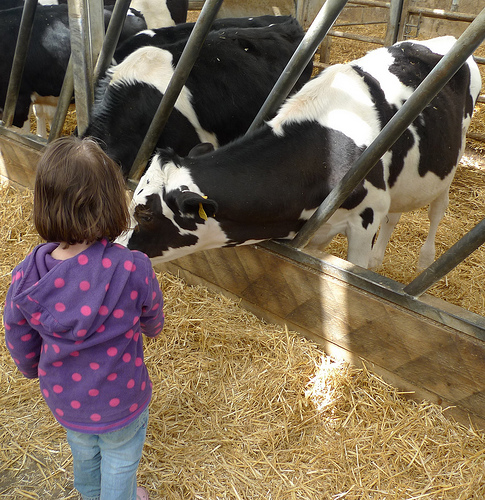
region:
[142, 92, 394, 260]
the cow is white and black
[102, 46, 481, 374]
the cow is white and black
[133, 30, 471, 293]
a black and white cow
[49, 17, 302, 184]
a black and white cow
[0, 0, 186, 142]
a black and white cow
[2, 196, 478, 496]
floor covered in brown hay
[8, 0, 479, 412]
a metal separating gate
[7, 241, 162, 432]
a purple and pink hoodie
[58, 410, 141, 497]
a pair of girl's blue jeans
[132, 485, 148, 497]
a pink shoe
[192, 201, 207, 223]
a yellow ear tag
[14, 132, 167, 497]
a young girl feeding cow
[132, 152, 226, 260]
Head of a cow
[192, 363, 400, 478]
Hay on the ground of the shed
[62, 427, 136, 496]
A pair of jeans pants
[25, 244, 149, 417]
Dotten jersey with a hood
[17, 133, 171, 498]
The back of a child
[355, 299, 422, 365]
Frame of wood forming and embarkment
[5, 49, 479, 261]
Cows in a shed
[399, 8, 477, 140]
Metal support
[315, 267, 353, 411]
Streak of light falling into the shed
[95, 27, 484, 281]
THE COW IS BLACK AND WHITE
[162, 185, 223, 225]
THE COW HAS A BLACK EAR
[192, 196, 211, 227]
THE COWS HAS A YELLOW TAG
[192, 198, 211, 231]
THE TAG IS ON THE COW'S EAR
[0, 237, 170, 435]
THE GIRL IS WEARING A JACKET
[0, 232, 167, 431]
THE JACKET IS PURPLE WITH PINK DOTS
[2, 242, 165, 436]
THE JACKET HAS A HOOD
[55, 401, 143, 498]
THE LITTLE GIRL IS WEARING JEANS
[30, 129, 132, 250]
THE LITTLE GIRL HAS BROWN HAIR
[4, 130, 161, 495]
THE LITTLE GIRL IS FEEDING THE COW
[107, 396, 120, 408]
pink polka dot on jacket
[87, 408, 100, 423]
pink polka dot on jacket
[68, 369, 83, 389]
pink polka dot on jacket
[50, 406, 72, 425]
pink polka dot on jacket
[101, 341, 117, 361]
pink polka dot on jacket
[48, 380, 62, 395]
pink polka dot on jacket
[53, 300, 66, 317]
pink polka dot on jacket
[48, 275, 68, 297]
pink polka dot on jacket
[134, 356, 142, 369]
pink polka dot on jacket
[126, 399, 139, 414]
pink polka dot on jacket